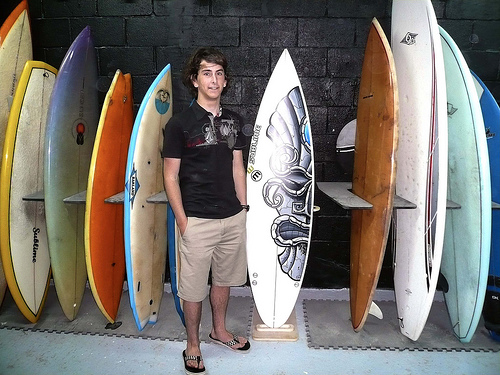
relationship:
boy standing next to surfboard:
[162, 48, 251, 373] [83, 65, 133, 325]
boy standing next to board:
[162, 48, 251, 373] [126, 63, 170, 331]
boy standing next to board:
[162, 48, 251, 373] [43, 25, 96, 321]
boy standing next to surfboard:
[162, 48, 251, 373] [245, 44, 311, 328]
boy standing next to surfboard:
[162, 48, 251, 373] [348, 16, 400, 334]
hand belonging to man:
[179, 219, 200, 248] [165, 45, 255, 362]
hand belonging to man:
[240, 210, 248, 232] [165, 45, 255, 362]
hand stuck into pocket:
[179, 219, 200, 248] [176, 214, 206, 251]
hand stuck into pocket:
[240, 210, 248, 232] [234, 206, 248, 239]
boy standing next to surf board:
[162, 48, 251, 373] [245, 47, 314, 329]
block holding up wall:
[238, 18, 296, 43] [2, 0, 499, 289]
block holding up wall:
[300, 17, 355, 48] [2, 0, 499, 289]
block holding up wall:
[181, 15, 239, 45] [2, 0, 499, 289]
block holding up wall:
[124, 17, 180, 47] [2, 0, 499, 289]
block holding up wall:
[223, 44, 270, 75] [2, 0, 499, 289]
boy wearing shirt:
[162, 48, 254, 373] [162, 99, 244, 221]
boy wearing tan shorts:
[162, 48, 251, 373] [169, 200, 254, 296]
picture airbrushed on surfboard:
[267, 153, 300, 247] [240, 89, 300, 256]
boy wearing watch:
[162, 48, 251, 373] [238, 202, 253, 211]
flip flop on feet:
[209, 333, 251, 351] [133, 322, 301, 374]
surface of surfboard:
[263, 85, 306, 307] [245, 44, 311, 328]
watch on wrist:
[241, 203, 249, 212] [238, 200, 248, 216]